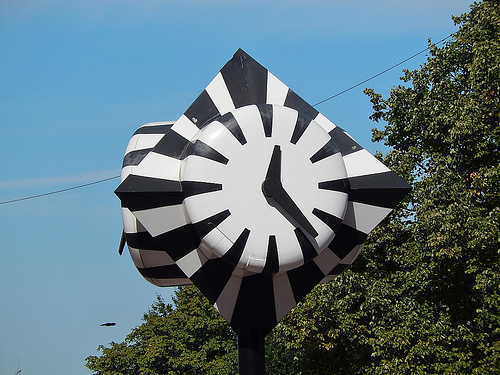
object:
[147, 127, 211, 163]
stripes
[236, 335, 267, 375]
pole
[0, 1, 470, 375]
sky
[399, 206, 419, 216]
branch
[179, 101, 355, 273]
clock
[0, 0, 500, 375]
picture taken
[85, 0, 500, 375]
green trees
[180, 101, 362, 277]
clock face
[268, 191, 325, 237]
minute hand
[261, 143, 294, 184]
hour hand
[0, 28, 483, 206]
telephone line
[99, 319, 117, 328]
bird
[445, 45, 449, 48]
tree branches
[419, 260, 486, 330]
black hole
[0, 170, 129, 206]
power lines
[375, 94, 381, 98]
tree leaves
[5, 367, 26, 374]
top of streetlight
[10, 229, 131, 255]
thin clouds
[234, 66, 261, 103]
black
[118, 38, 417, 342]
outside clock